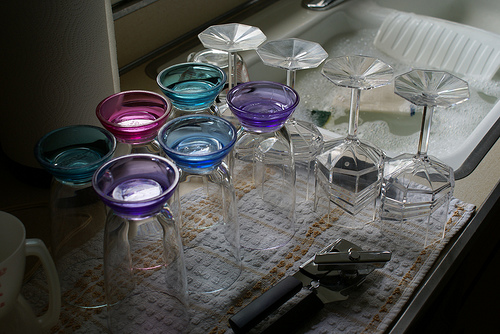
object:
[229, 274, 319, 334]
handle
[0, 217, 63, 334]
coffee mug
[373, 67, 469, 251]
wine glas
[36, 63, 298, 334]
drinking glass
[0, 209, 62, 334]
measuring cup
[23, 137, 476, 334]
towel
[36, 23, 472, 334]
clouds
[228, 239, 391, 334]
can opener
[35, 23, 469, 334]
glass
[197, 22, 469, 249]
stemware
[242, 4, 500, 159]
sink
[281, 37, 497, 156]
water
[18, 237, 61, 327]
handle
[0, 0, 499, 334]
counter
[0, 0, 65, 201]
corner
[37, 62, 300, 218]
base